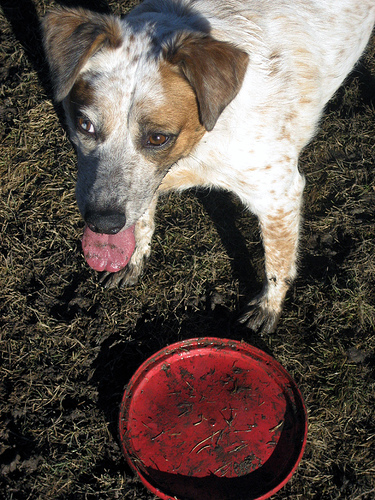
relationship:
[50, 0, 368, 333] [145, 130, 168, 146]
dog has eye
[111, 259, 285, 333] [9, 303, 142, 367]
paws on ground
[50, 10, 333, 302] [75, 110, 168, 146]
dog has eyes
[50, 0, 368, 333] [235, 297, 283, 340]
dog has dog's paw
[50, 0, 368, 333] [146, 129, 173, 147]
dog has brown eye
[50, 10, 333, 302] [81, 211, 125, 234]
dog has nose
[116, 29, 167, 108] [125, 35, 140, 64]
fur has spots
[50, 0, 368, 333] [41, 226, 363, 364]
dog standing in grass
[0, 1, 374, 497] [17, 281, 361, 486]
grass on ground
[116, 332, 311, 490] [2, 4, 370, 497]
frisbee on ground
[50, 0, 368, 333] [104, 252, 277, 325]
dog has paws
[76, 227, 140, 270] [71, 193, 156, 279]
tongue hanging out of mouth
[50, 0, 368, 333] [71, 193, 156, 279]
dog has mouth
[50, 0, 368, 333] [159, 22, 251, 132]
dog has ear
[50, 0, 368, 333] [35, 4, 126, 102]
dog has ear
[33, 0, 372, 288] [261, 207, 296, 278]
fur has spots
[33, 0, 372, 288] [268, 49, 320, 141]
fur has spots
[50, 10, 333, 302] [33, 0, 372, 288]
dog has fur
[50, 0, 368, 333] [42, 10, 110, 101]
dog has ear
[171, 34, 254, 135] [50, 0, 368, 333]
ear on dog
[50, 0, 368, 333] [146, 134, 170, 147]
dog has brown eye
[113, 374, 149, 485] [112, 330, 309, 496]
edge on floater